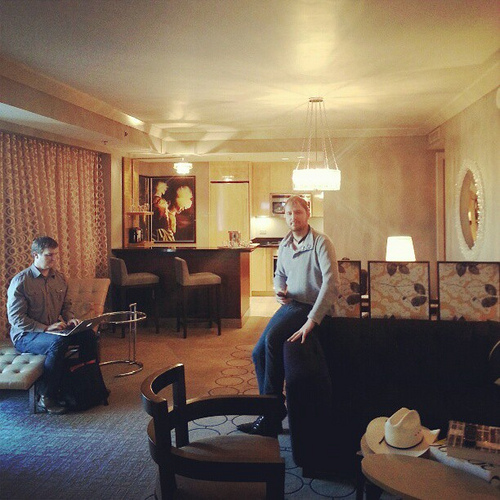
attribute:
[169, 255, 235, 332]
stool — padded 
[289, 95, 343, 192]
chandelier — lit, hanging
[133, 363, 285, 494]
chair — wooded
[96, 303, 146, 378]
table — chrome, glass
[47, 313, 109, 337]
computer — apple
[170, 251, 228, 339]
stool — padded 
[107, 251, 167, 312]
stool — padded 